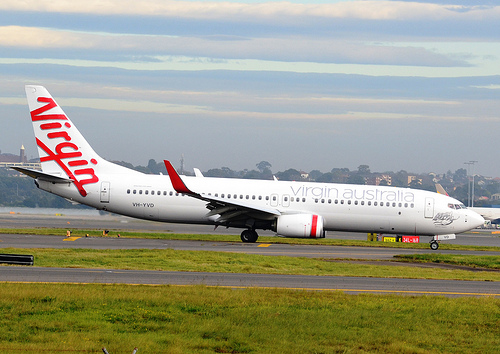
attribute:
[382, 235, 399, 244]
sign — yellow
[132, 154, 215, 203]
wing — airplane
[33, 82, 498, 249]
jet — Virgin airline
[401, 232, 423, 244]
sign — orange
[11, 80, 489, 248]
airplane — red, white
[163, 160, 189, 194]
winglet — red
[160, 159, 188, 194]
upturned tip — red